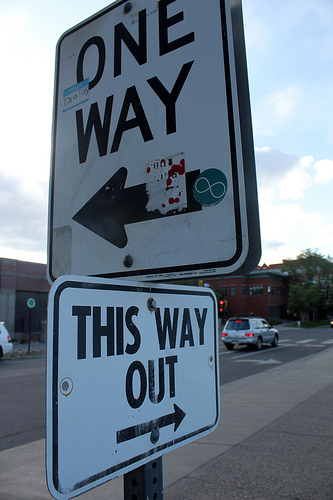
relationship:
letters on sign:
[74, 14, 208, 167] [45, 0, 262, 278]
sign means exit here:
[47, 282, 228, 487] [73, 301, 212, 445]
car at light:
[217, 314, 283, 353] [219, 295, 232, 318]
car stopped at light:
[217, 314, 283, 353] [219, 295, 232, 318]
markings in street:
[232, 328, 329, 366] [6, 325, 322, 496]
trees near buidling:
[282, 249, 329, 324] [218, 258, 315, 320]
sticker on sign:
[191, 166, 225, 212] [45, 0, 262, 278]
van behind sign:
[2, 321, 18, 359] [45, 0, 262, 278]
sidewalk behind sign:
[2, 347, 332, 493] [45, 0, 262, 278]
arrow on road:
[228, 357, 284, 365] [0, 318, 332, 448]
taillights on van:
[221, 327, 258, 339] [223, 314, 286, 350]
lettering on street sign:
[68, 0, 210, 178] [47, 0, 246, 281]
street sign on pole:
[47, 0, 246, 281] [118, 455, 169, 497]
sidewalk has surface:
[2, 347, 332, 493] [2, 343, 331, 497]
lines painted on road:
[240, 336, 317, 367] [0, 318, 332, 448]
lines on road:
[240, 336, 317, 367] [0, 318, 332, 448]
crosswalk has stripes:
[232, 328, 330, 350] [279, 331, 329, 353]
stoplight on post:
[217, 295, 226, 314] [219, 286, 228, 325]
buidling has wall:
[218, 258, 315, 320] [1, 262, 50, 349]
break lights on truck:
[219, 330, 256, 341] [221, 316, 283, 352]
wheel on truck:
[251, 338, 267, 348] [221, 316, 283, 352]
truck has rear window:
[221, 316, 283, 352] [228, 317, 250, 330]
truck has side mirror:
[221, 316, 283, 352] [266, 321, 276, 331]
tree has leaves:
[284, 275, 327, 333] [286, 273, 324, 307]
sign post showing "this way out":
[49, 277, 229, 482] [73, 291, 212, 462]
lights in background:
[216, 298, 225, 314] [0, 1, 332, 367]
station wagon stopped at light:
[221, 313, 281, 354] [219, 295, 232, 318]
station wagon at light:
[221, 313, 281, 354] [219, 295, 232, 318]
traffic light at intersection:
[216, 296, 224, 315] [219, 318, 329, 360]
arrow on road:
[234, 352, 287, 368] [0, 318, 332, 448]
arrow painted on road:
[234, 352, 287, 368] [0, 318, 332, 448]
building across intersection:
[213, 253, 330, 324] [219, 318, 329, 360]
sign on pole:
[45, 0, 262, 278] [118, 455, 169, 497]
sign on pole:
[47, 282, 228, 487] [118, 455, 169, 497]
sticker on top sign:
[191, 166, 225, 212] [49, 0, 262, 282]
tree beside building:
[284, 275, 327, 333] [213, 253, 330, 324]